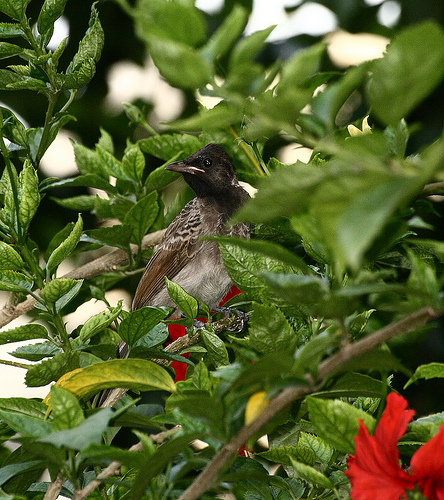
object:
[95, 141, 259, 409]
bird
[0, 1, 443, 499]
plant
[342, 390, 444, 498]
flower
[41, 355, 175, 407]
leaf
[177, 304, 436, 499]
branch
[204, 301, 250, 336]
claw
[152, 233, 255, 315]
belly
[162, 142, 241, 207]
head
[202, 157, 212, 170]
eye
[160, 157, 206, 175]
beak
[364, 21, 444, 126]
leaf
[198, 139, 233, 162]
mohawk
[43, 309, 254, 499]
branch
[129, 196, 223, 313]
wing